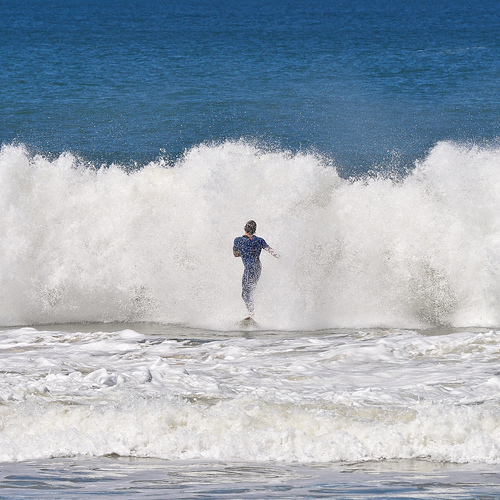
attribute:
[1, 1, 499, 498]
ocean — body of water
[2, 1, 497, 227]
water — white, frothy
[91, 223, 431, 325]
wave — spray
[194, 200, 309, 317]
wet suit — black, blue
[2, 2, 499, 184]
water — blue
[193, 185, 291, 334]
man — surfing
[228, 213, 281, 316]
surfer — riding 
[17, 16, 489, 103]
water — splashing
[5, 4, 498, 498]
water — blue-gray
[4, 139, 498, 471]
portion — white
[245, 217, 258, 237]
hair — black